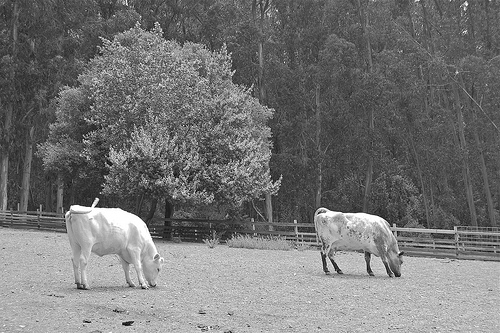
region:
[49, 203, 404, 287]
two cows eating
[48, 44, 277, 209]
a nice leafy tree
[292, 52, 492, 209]
the forest in the background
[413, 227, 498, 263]
the wodden stacked pattern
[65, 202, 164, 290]
a white cow eating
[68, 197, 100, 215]
the tail of the white cat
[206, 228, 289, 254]
some grass in the field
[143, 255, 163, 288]
the head of the white cow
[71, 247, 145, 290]
the four legs of the cow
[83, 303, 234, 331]
several rocks in the field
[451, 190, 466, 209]
part of a forest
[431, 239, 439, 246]
part of the fence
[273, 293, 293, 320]
part of the field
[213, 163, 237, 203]
edge of a tree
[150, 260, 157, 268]
face of a cow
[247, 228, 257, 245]
part of the bush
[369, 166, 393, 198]
part of the forest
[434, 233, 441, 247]
part of a fence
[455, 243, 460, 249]
part of a fence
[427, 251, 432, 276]
edge of a fecne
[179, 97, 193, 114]
edge of a tree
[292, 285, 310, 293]
part of a surface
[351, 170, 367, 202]
part of a forest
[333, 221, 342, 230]
back of a cow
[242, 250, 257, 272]
part of the ground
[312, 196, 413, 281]
spotted cow eating grass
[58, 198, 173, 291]
white cow eating grass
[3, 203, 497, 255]
wooden fence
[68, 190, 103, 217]
cow's tail is moving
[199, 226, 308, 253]
some tall brush in the field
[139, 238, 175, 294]
cow's head is bent down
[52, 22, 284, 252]
leafy tree outside the fence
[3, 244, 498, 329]
short grass inside the fence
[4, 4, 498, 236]
lots of tall trees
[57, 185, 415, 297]
two cows in a field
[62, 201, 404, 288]
pigs eating grass on flat ground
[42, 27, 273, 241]
large round tree covered with leaves by fence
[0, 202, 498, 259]
wood fence with posts and horizontal slats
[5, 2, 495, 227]
forest of tall trees in back of fence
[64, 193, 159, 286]
white pig with tail curled over rear of body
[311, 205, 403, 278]
spotted pig with dark legs and curved tail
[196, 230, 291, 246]
short plants growing near fence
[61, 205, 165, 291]
pig with head bent down to the ground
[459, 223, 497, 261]
mesh in back of a section of fence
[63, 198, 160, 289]
faint shadow between pig's legs